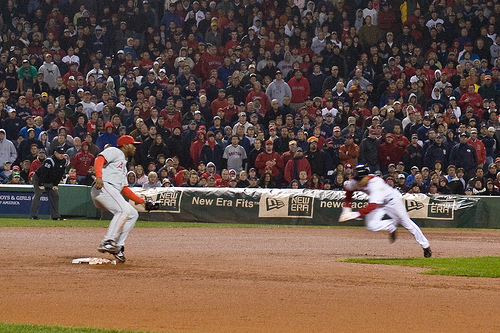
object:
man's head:
[116, 134, 142, 157]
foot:
[97, 239, 127, 262]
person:
[283, 146, 312, 188]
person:
[257, 172, 279, 188]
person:
[265, 69, 292, 109]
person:
[286, 69, 311, 110]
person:
[307, 62, 329, 101]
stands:
[63, 8, 475, 208]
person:
[458, 82, 485, 113]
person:
[35, 52, 61, 90]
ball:
[270, 98, 279, 109]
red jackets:
[283, 156, 313, 183]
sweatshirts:
[253, 150, 285, 179]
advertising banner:
[98, 186, 482, 231]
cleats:
[96, 239, 126, 263]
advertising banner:
[0, 186, 58, 218]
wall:
[51, 187, 104, 219]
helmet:
[351, 164, 371, 181]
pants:
[363, 189, 431, 249]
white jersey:
[343, 174, 403, 206]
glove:
[144, 200, 161, 211]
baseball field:
[14, 207, 498, 329]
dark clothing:
[29, 145, 70, 221]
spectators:
[4, 6, 157, 100]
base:
[69, 257, 117, 266]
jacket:
[35, 154, 67, 187]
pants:
[29, 172, 62, 218]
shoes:
[29, 214, 67, 221]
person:
[220, 136, 250, 172]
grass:
[340, 253, 500, 280]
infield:
[341, 207, 497, 254]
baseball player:
[338, 163, 433, 258]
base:
[292, 235, 331, 282]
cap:
[116, 135, 141, 147]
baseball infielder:
[90, 134, 147, 263]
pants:
[90, 183, 140, 245]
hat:
[54, 145, 67, 154]